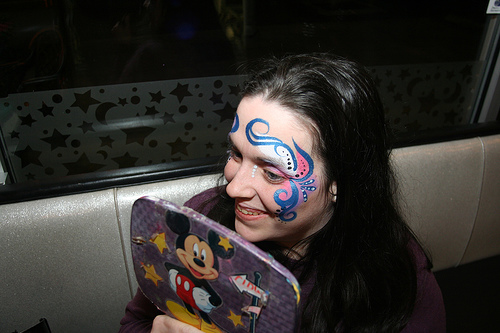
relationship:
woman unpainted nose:
[117, 52, 445, 333] [225, 172, 253, 200]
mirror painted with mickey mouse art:
[129, 197, 300, 333] [164, 211, 233, 331]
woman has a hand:
[225, 51, 446, 332] [150, 315, 204, 332]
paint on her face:
[231, 112, 318, 223] [223, 95, 327, 243]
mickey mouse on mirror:
[164, 211, 233, 331] [129, 197, 300, 333]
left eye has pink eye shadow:
[262, 166, 285, 185] [263, 165, 287, 180]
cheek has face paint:
[271, 183, 317, 222] [242, 118, 316, 222]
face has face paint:
[223, 95, 327, 243] [242, 118, 316, 222]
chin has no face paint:
[233, 216, 270, 242] [242, 118, 316, 222]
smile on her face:
[232, 201, 269, 222] [223, 95, 327, 243]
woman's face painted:
[225, 51, 446, 332] [223, 95, 327, 243]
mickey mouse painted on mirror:
[164, 211, 233, 331] [129, 197, 300, 333]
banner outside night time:
[1, 80, 228, 184] [1, 2, 220, 171]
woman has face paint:
[225, 51, 446, 332] [242, 118, 316, 222]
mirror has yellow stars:
[129, 197, 300, 333] [141, 261, 163, 287]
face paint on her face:
[242, 118, 316, 222] [223, 95, 327, 243]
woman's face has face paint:
[225, 51, 446, 332] [242, 118, 316, 222]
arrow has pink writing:
[229, 276, 270, 304] [235, 276, 262, 297]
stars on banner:
[70, 88, 99, 114] [1, 80, 228, 184]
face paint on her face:
[228, 111, 318, 171] [223, 95, 327, 243]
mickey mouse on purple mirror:
[164, 211, 233, 331] [129, 197, 300, 333]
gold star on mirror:
[141, 261, 163, 287] [129, 197, 300, 333]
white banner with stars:
[1, 80, 228, 184] [169, 82, 192, 103]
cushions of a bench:
[422, 134, 499, 266] [1, 168, 127, 331]